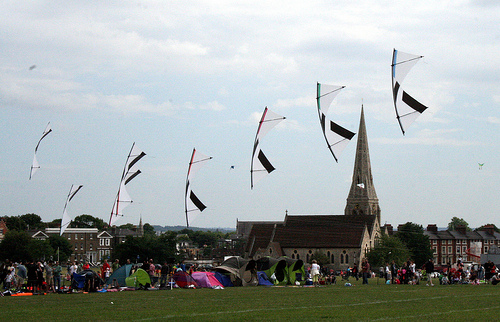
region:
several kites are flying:
[211, 51, 473, 213]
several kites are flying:
[182, 34, 482, 318]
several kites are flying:
[127, 74, 318, 288]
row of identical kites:
[161, 46, 426, 223]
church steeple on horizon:
[343, 98, 381, 201]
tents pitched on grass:
[208, 252, 302, 288]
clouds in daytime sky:
[141, 13, 269, 96]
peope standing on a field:
[37, 259, 96, 294]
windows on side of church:
[288, 244, 358, 270]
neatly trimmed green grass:
[156, 291, 246, 315]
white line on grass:
[314, 294, 384, 314]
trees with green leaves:
[118, 231, 183, 260]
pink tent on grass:
[187, 266, 225, 292]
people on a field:
[0, 250, 499, 295]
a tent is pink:
[161, 260, 225, 295]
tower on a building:
[341, 92, 385, 217]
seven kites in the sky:
[20, 37, 440, 237]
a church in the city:
[231, 99, 391, 266]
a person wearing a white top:
[308, 254, 323, 284]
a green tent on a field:
[254, 254, 309, 290]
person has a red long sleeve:
[96, 250, 113, 282]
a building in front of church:
[40, 221, 120, 267]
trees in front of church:
[367, 214, 433, 265]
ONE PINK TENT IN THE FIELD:
[186, 265, 224, 290]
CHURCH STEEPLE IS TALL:
[341, 100, 383, 227]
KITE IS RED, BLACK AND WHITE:
[187, 141, 214, 229]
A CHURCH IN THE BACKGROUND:
[218, 100, 391, 272]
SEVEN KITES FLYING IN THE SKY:
[14, 47, 433, 239]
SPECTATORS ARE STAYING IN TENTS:
[86, 251, 323, 284]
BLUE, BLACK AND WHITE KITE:
[296, 56, 373, 168]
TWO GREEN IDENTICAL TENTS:
[256, 250, 306, 280]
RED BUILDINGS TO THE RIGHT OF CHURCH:
[426, 225, 496, 265]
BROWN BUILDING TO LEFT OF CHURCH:
[18, 223, 113, 264]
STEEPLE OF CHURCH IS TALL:
[348, 103, 393, 252]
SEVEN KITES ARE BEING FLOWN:
[16, 34, 426, 249]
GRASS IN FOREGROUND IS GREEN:
[2, 280, 498, 319]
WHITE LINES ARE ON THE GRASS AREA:
[26, 291, 494, 318]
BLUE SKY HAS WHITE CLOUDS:
[5, 3, 478, 115]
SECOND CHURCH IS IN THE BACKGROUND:
[111, 220, 153, 242]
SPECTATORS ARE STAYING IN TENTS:
[2, 260, 326, 292]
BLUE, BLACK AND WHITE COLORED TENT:
[284, 69, 380, 161]